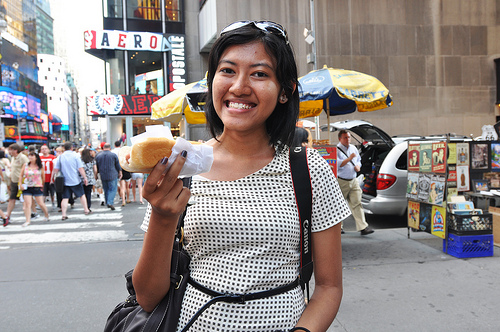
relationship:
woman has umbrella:
[127, 19, 355, 331] [298, 56, 418, 153]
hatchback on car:
[319, 113, 393, 208] [327, 115, 464, 224]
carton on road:
[447, 236, 492, 253] [0, 193, 500, 331]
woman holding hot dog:
[183, 19, 339, 188] [114, 130, 187, 172]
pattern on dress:
[179, 139, 349, 329] [178, 169, 347, 294]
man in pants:
[332, 125, 376, 237] [340, 175, 370, 231]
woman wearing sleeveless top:
[19, 146, 55, 228] [21, 164, 44, 187]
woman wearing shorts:
[19, 146, 55, 228] [22, 186, 42, 196]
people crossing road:
[0, 143, 122, 209] [0, 193, 500, 331]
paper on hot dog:
[165, 143, 217, 186] [85, 97, 242, 212]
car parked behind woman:
[327, 116, 475, 218] [136, 16, 347, 321]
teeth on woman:
[222, 98, 254, 110] [136, 16, 347, 321]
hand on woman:
[136, 140, 196, 225] [115, 12, 361, 331]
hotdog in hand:
[99, 122, 227, 203] [119, 157, 216, 228]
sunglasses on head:
[208, 12, 303, 39] [191, 22, 313, 129]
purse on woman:
[102, 144, 206, 330] [136, 16, 347, 321]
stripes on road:
[6, 197, 136, 252] [18, 250, 78, 324]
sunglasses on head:
[216, 18, 289, 45] [201, 21, 299, 131]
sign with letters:
[83, 20, 183, 110] [65, 20, 240, 62]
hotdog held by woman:
[117, 135, 210, 175] [136, 16, 347, 321]